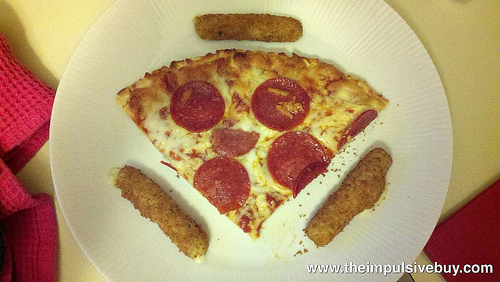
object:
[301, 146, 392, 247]
mozzarella stick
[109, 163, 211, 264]
mozzarella stick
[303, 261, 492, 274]
address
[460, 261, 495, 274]
.com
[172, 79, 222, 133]
pepperoni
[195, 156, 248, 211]
pepperoni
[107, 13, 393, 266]
food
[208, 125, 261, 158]
pepperoni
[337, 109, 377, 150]
pepperoni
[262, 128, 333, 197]
pepperoni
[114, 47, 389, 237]
pizza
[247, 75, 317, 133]
pepperoni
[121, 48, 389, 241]
cheese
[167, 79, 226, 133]
pepperoni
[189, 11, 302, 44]
cheese stick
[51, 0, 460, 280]
plate